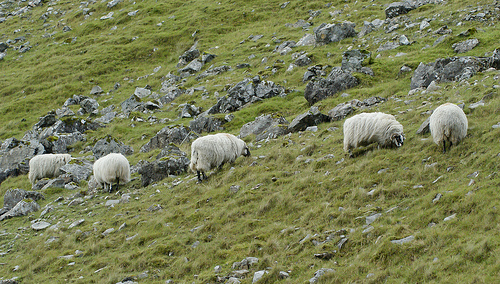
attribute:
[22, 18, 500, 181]
rocks — gray, small, large, scattered, mixed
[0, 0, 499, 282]
grass — green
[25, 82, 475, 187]
sheep — white, tan, grazing, eating, enjoying, grouped, wandering, leaning, fluffy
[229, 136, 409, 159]
heads — black, white